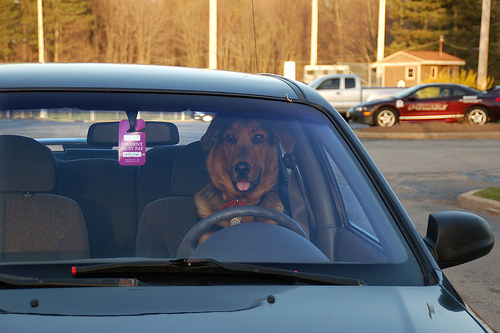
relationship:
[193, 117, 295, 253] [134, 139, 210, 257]
dog in seat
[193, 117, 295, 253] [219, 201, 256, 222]
dog wearing collar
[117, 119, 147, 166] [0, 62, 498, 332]
permit in car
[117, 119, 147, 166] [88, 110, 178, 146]
permit hanging on mirror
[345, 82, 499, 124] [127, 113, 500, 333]
car on road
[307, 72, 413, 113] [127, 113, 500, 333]
truck on road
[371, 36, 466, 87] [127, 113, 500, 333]
house beside road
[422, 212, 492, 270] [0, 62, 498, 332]
mirror on car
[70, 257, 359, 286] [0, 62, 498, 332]
wiper on car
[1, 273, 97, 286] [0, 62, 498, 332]
wiper on car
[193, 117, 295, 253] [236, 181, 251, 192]
dog shows toungue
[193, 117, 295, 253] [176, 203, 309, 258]
dog behind steering wheel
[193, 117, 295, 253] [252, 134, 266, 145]
dog has eye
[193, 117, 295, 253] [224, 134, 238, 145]
dog has eye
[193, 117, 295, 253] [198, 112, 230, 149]
dog has ear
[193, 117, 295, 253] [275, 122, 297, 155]
dog has ear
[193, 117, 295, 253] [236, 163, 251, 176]
dog has nose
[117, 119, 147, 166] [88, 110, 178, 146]
permit on mirror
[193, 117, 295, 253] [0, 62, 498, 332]
dog sitting in car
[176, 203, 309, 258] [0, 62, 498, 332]
steering wheel in car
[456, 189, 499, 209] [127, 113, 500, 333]
curb in road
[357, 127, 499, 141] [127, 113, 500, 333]
curb in road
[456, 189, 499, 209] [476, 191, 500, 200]
curb has grass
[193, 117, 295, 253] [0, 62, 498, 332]
dog in car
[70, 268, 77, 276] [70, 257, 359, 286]
tip on wiper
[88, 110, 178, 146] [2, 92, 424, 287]
mirror on windshield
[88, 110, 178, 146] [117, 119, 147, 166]
mirror holds permit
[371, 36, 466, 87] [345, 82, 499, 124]
house behind car